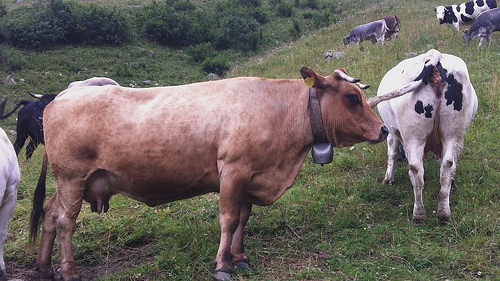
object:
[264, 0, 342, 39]
bushes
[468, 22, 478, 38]
neck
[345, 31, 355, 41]
neck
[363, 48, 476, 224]
cow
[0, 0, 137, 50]
bush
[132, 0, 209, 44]
bush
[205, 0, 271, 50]
bush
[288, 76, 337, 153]
neck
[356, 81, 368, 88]
horns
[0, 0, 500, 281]
grass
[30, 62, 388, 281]
brown cow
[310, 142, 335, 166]
bell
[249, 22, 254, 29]
hill side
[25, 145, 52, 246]
tail tip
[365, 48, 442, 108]
tail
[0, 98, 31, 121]
tail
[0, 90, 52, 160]
cow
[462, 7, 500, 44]
cow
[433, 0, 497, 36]
cow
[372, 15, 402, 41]
cow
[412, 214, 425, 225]
hoof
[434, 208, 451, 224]
hoof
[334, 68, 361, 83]
horn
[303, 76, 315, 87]
tag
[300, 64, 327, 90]
ear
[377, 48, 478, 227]
backside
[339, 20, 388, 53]
cow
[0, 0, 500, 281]
field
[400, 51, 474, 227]
behind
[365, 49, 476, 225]
rear